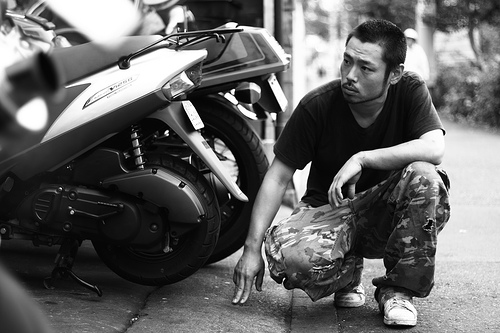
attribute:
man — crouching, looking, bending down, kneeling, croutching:
[219, 2, 451, 321]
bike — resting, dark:
[4, 21, 279, 274]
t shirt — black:
[262, 67, 461, 217]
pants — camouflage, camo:
[266, 164, 451, 296]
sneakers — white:
[329, 266, 419, 327]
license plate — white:
[176, 98, 213, 132]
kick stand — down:
[57, 262, 111, 302]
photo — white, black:
[2, 3, 499, 330]